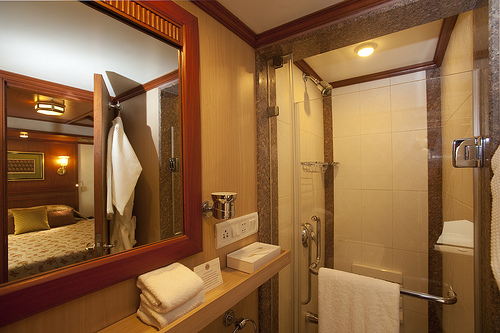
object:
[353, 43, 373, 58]
fixture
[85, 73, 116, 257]
door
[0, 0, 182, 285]
mirror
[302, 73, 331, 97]
shower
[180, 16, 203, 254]
frame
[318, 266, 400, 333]
towel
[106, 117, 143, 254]
robe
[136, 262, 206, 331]
towel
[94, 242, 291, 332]
shelf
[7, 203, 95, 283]
bed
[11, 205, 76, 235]
pillows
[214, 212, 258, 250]
outlet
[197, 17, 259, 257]
wall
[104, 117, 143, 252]
towel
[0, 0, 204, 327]
wood frame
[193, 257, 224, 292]
sign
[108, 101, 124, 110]
hook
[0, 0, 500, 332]
bathroom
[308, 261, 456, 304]
bar